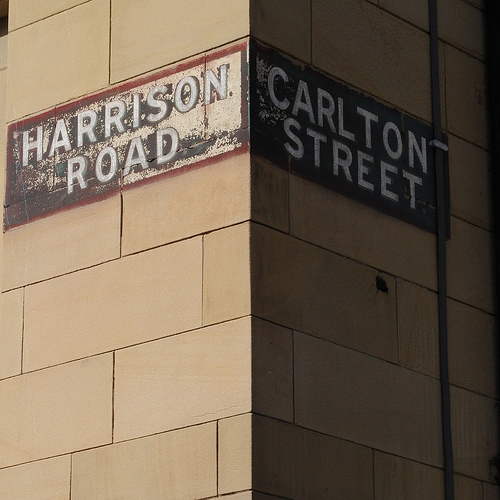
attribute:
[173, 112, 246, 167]
black paint — fading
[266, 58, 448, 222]
writing — white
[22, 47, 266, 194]
sign — red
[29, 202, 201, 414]
wall — beige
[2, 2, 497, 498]
building — large, bricks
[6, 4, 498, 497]
wall — patterned, tile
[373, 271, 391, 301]
hole — black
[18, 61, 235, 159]
sign — black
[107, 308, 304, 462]
brick — beige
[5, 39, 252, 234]
sign — red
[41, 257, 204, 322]
tile — square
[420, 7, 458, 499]
wire — long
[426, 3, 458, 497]
pipe — steel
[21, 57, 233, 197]
word — white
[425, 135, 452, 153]
bracket — metallic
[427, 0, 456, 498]
cord — black